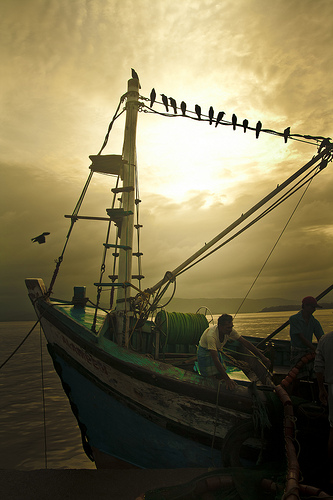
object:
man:
[289, 296, 325, 379]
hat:
[302, 296, 322, 308]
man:
[192, 309, 270, 380]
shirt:
[199, 326, 242, 351]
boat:
[27, 63, 332, 467]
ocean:
[4, 312, 333, 470]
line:
[138, 92, 324, 145]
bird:
[150, 88, 157, 107]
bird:
[255, 121, 263, 140]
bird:
[231, 113, 237, 131]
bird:
[168, 96, 179, 114]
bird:
[195, 104, 202, 120]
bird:
[180, 100, 186, 115]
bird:
[160, 94, 171, 113]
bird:
[131, 68, 142, 89]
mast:
[113, 77, 140, 345]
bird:
[31, 231, 50, 245]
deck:
[228, 357, 312, 386]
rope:
[170, 308, 207, 342]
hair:
[218, 314, 232, 325]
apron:
[197, 345, 226, 376]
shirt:
[290, 310, 325, 345]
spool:
[150, 305, 217, 360]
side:
[39, 311, 241, 467]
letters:
[62, 336, 69, 345]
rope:
[2, 319, 42, 369]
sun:
[133, 71, 291, 206]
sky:
[2, 1, 331, 311]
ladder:
[89, 168, 129, 336]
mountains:
[255, 295, 333, 317]